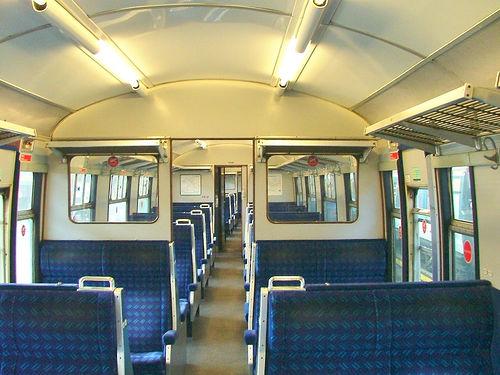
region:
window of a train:
[76, 148, 160, 218]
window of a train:
[264, 152, 366, 223]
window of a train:
[451, 165, 489, 216]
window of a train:
[443, 228, 484, 280]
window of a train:
[401, 182, 447, 275]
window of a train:
[381, 216, 409, 282]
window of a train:
[9, 160, 39, 202]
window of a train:
[69, 174, 99, 204]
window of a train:
[115, 171, 135, 199]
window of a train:
[134, 180, 156, 201]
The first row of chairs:
[16, 269, 498, 373]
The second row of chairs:
[47, 223, 422, 350]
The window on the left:
[59, 151, 173, 236]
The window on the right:
[260, 141, 387, 241]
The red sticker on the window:
[300, 149, 324, 176]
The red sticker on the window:
[457, 238, 474, 270]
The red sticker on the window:
[417, 215, 431, 236]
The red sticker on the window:
[19, 219, 30, 239]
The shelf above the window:
[365, 86, 496, 161]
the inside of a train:
[65, 106, 421, 369]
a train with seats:
[52, 135, 408, 367]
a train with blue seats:
[47, 72, 344, 352]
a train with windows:
[319, 96, 485, 273]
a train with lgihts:
[82, 6, 393, 106]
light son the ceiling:
[52, 15, 417, 198]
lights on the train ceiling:
[51, 10, 378, 193]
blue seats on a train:
[86, 178, 493, 366]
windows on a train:
[365, 189, 495, 345]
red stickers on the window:
[389, 193, 492, 290]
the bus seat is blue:
[276, 301, 483, 368]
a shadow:
[199, 307, 241, 344]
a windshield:
[73, 162, 160, 224]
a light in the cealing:
[280, 53, 307, 85]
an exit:
[16, 152, 33, 166]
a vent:
[443, 110, 478, 132]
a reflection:
[168, 5, 232, 25]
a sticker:
[454, 237, 474, 263]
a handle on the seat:
[265, 275, 302, 285]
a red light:
[300, 155, 321, 166]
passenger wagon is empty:
[6, 93, 446, 366]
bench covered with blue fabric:
[0, 278, 124, 374]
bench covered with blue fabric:
[250, 267, 495, 369]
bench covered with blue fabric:
[38, 237, 179, 282]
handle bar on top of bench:
[72, 271, 119, 296]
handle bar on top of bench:
[269, 273, 308, 294]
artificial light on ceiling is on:
[85, 32, 317, 92]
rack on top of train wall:
[365, 83, 497, 155]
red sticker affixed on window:
[460, 237, 476, 263]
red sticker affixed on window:
[300, 153, 325, 172]